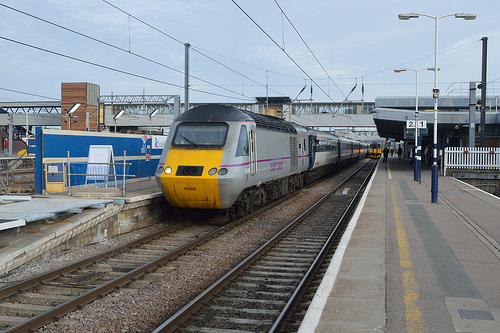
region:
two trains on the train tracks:
[152, 86, 392, 219]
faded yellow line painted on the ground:
[390, 195, 425, 332]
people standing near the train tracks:
[380, 141, 406, 163]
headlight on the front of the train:
[163, 162, 174, 177]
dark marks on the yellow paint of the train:
[166, 189, 226, 207]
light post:
[393, 4, 473, 206]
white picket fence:
[443, 142, 496, 169]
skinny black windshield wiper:
[176, 131, 199, 147]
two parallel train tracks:
[0, 240, 308, 331]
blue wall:
[32, 119, 158, 193]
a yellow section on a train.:
[149, 141, 225, 209]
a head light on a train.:
[160, 164, 182, 181]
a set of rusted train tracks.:
[151, 154, 376, 331]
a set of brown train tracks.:
[1, 156, 346, 331]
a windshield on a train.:
[169, 116, 241, 158]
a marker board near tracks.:
[72, 134, 118, 195]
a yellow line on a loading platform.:
[379, 164, 437, 331]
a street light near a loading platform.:
[394, 7, 484, 202]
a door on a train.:
[241, 114, 273, 188]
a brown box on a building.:
[46, 76, 112, 136]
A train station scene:
[15, 33, 491, 331]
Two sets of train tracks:
[69, 233, 311, 320]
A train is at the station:
[157, 94, 368, 209]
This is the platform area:
[366, 98, 476, 331]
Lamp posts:
[392, 7, 479, 207]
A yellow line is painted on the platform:
[379, 175, 424, 331]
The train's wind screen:
[169, 121, 234, 154]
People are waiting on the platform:
[382, 139, 405, 170]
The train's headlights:
[153, 162, 231, 182]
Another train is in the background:
[366, 138, 386, 162]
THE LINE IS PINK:
[236, 159, 245, 170]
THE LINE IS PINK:
[234, 160, 241, 173]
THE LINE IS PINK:
[231, 160, 258, 208]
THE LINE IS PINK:
[228, 157, 238, 181]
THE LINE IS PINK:
[238, 155, 243, 170]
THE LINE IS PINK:
[242, 160, 250, 176]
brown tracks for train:
[237, 232, 318, 293]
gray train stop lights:
[420, 33, 475, 154]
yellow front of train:
[153, 153, 231, 217]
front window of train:
[158, 115, 244, 153]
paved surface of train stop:
[105, 176, 165, 198]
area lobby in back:
[285, 80, 403, 140]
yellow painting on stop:
[379, 189, 444, 314]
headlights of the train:
[202, 150, 248, 190]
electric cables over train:
[82, 13, 172, 92]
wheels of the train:
[237, 180, 341, 208]